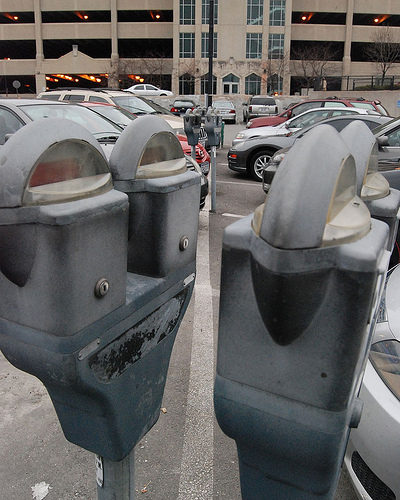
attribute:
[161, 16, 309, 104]
apartment — white, large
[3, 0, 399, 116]
building — large, lit, white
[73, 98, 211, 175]
car — is red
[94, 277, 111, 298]
hole — silver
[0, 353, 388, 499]
littered tarmac — gray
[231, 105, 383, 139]
car — white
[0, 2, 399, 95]
building — large